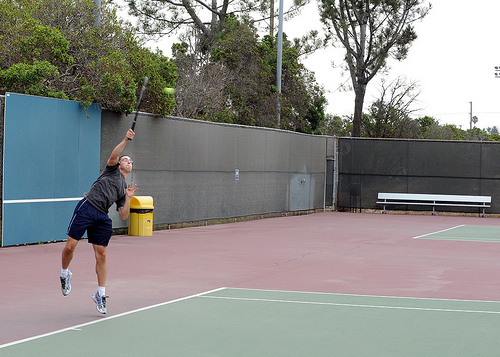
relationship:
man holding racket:
[93, 133, 149, 207] [119, 68, 152, 140]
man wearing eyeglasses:
[93, 133, 149, 207] [122, 155, 135, 168]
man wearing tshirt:
[93, 133, 149, 207] [83, 166, 134, 212]